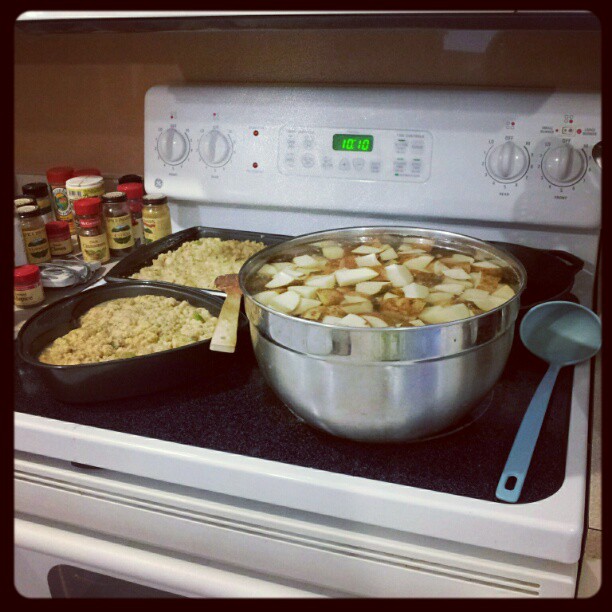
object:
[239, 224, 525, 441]
bowl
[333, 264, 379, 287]
potato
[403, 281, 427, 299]
potato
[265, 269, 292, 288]
potato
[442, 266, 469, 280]
potato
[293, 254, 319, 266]
potato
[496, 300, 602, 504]
ladle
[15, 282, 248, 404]
pan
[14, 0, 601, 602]
stove